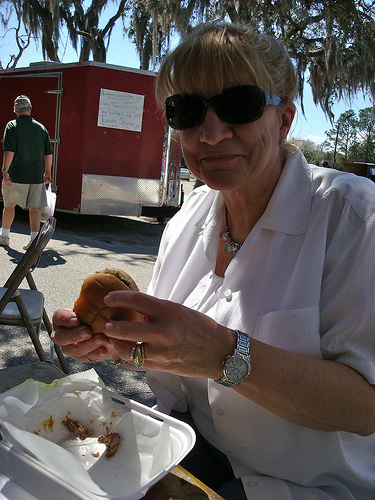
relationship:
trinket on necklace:
[216, 228, 238, 254] [214, 219, 242, 254]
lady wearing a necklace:
[56, 13, 373, 498] [214, 219, 242, 254]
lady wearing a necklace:
[56, 13, 373, 498] [219, 223, 244, 261]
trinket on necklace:
[216, 228, 238, 254] [219, 223, 244, 261]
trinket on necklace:
[216, 228, 238, 254] [217, 222, 256, 257]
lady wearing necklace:
[56, 13, 373, 498] [217, 222, 256, 257]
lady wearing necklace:
[56, 13, 373, 498] [219, 230, 248, 258]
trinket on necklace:
[224, 238, 238, 255] [219, 230, 248, 258]